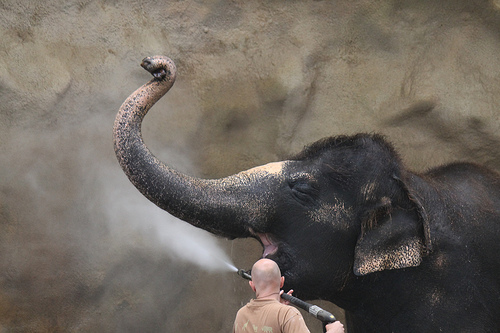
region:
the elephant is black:
[125, 114, 496, 306]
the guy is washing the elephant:
[210, 260, 342, 332]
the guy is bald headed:
[242, 262, 294, 292]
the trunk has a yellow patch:
[169, 147, 301, 188]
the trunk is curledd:
[114, 99, 283, 210]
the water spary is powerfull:
[232, 252, 324, 331]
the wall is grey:
[26, 132, 113, 296]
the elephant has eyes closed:
[246, 160, 492, 306]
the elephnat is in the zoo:
[102, 100, 499, 323]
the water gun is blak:
[289, 294, 333, 323]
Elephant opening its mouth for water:
[101, 29, 319, 325]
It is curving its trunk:
[102, 57, 226, 187]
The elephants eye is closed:
[283, 182, 330, 201]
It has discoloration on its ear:
[355, 179, 460, 289]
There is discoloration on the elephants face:
[307, 200, 357, 231]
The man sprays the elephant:
[220, 256, 300, 331]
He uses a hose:
[225, 266, 300, 319]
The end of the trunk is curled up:
[126, 40, 257, 171]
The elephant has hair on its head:
[310, 121, 431, 149]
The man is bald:
[246, 263, 291, 313]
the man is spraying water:
[167, 238, 353, 321]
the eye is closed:
[252, 150, 344, 222]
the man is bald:
[220, 247, 290, 301]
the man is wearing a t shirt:
[186, 250, 304, 327]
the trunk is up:
[84, 42, 281, 232]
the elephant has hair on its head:
[269, 106, 411, 186]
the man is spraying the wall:
[78, 189, 296, 317]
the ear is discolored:
[313, 173, 440, 280]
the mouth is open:
[207, 205, 299, 292]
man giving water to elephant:
[223, 251, 350, 331]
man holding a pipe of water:
[147, 204, 350, 330]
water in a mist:
[57, 108, 342, 331]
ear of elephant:
[340, 161, 444, 285]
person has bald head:
[228, 251, 343, 329]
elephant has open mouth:
[180, 144, 330, 291]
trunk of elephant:
[101, 33, 251, 249]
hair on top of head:
[291, 121, 413, 198]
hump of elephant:
[430, 149, 498, 194]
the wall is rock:
[7, 7, 497, 324]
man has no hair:
[245, 258, 302, 312]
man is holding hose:
[230, 254, 300, 321]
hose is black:
[243, 259, 349, 327]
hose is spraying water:
[164, 233, 332, 320]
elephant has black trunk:
[119, 107, 268, 242]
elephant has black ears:
[323, 102, 471, 324]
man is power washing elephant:
[70, 176, 327, 324]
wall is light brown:
[41, 178, 141, 301]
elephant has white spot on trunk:
[242, 131, 289, 188]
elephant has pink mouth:
[240, 202, 290, 274]